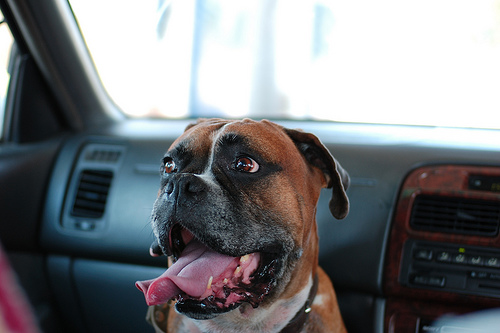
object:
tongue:
[143, 249, 229, 306]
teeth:
[207, 275, 214, 290]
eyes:
[228, 155, 269, 175]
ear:
[287, 126, 353, 223]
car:
[0, 0, 500, 333]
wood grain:
[422, 171, 454, 193]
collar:
[274, 266, 323, 331]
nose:
[162, 171, 206, 196]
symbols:
[454, 253, 465, 262]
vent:
[68, 168, 114, 219]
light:
[458, 246, 468, 255]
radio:
[407, 260, 500, 299]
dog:
[128, 117, 356, 333]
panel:
[377, 164, 498, 333]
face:
[153, 123, 301, 315]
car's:
[368, 160, 500, 329]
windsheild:
[236, 9, 309, 127]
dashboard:
[465, 175, 499, 195]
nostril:
[181, 178, 195, 197]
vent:
[406, 193, 496, 238]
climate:
[413, 247, 434, 261]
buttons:
[434, 250, 451, 263]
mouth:
[148, 205, 274, 307]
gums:
[203, 258, 259, 297]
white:
[240, 313, 286, 326]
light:
[134, 27, 196, 73]